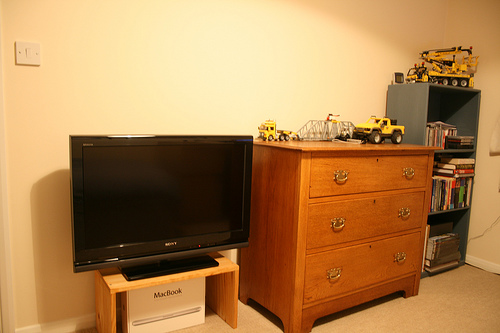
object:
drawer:
[303, 233, 421, 305]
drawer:
[308, 190, 425, 250]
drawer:
[309, 154, 429, 198]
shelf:
[424, 258, 465, 275]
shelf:
[428, 206, 470, 217]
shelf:
[431, 148, 476, 154]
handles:
[329, 218, 346, 229]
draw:
[307, 191, 425, 250]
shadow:
[31, 167, 70, 322]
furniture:
[238, 140, 445, 333]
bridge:
[290, 114, 355, 142]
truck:
[406, 45, 479, 88]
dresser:
[425, 84, 482, 276]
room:
[0, 13, 480, 333]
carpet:
[422, 294, 478, 318]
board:
[14, 42, 40, 65]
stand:
[118, 254, 219, 282]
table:
[104, 278, 127, 293]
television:
[71, 136, 254, 282]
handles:
[333, 169, 350, 183]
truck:
[258, 119, 299, 142]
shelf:
[387, 86, 430, 145]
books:
[431, 157, 475, 212]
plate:
[15, 42, 41, 67]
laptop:
[120, 278, 207, 329]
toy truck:
[353, 115, 405, 145]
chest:
[236, 140, 444, 332]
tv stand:
[93, 250, 240, 333]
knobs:
[333, 167, 415, 182]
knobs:
[330, 207, 411, 229]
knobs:
[327, 252, 406, 279]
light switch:
[15, 41, 41, 65]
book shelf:
[384, 84, 481, 278]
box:
[128, 275, 207, 332]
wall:
[1, 6, 442, 331]